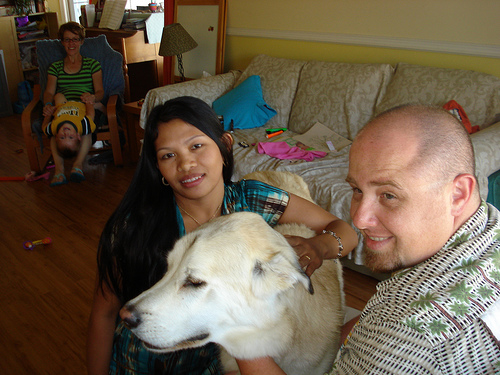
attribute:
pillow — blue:
[209, 72, 280, 136]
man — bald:
[300, 72, 493, 300]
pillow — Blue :
[213, 75, 276, 134]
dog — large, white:
[121, 170, 346, 373]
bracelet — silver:
[318, 221, 348, 256]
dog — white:
[83, 209, 378, 374]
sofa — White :
[137, 54, 497, 275]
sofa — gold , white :
[138, 41, 498, 255]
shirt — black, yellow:
[39, 88, 104, 142]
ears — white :
[250, 255, 315, 296]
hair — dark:
[116, 88, 247, 274]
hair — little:
[360, 97, 484, 206]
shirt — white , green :
[313, 194, 496, 371]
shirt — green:
[39, 55, 103, 105]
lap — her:
[28, 82, 105, 136]